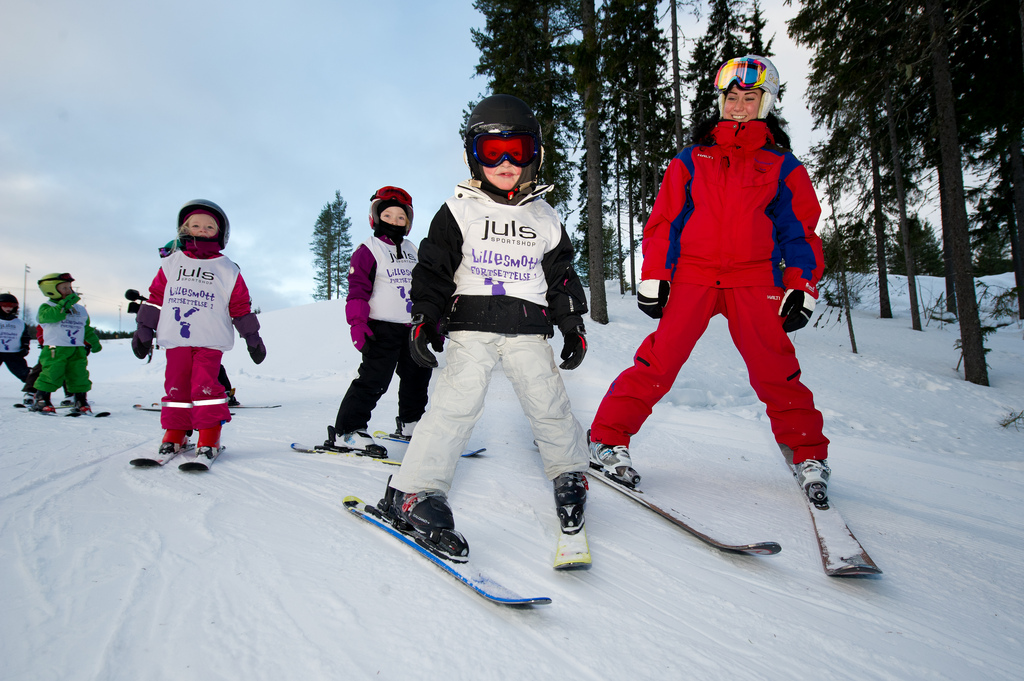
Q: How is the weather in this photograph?
A: It is cloudy.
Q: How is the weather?
A: It is cloudy.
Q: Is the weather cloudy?
A: Yes, it is cloudy.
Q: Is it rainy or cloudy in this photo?
A: It is cloudy.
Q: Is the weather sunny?
A: No, it is cloudy.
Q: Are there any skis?
A: Yes, there are skis.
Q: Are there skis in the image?
A: Yes, there are skis.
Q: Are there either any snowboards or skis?
A: Yes, there are skis.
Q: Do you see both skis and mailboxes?
A: No, there are skis but no mailboxes.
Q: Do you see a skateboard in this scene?
A: No, there are no skateboards.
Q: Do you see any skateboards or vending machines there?
A: No, there are no skateboards or vending machines.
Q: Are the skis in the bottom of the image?
A: Yes, the skis are in the bottom of the image.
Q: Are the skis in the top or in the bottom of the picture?
A: The skis are in the bottom of the image.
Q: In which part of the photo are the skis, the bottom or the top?
A: The skis are in the bottom of the image.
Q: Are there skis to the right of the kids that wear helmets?
A: Yes, there are skis to the right of the children.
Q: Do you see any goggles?
A: Yes, there are goggles.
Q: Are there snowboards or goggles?
A: Yes, there are goggles.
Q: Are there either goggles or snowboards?
A: Yes, there are goggles.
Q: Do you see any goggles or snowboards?
A: Yes, there are goggles.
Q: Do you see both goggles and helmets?
A: Yes, there are both goggles and a helmet.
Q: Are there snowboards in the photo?
A: No, there are no snowboards.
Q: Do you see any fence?
A: No, there are no fences.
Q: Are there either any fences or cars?
A: No, there are no fences or cars.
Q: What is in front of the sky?
A: The trees are in front of the sky.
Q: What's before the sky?
A: The trees are in front of the sky.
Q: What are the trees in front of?
A: The trees are in front of the sky.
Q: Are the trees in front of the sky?
A: Yes, the trees are in front of the sky.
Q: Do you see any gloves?
A: Yes, there are gloves.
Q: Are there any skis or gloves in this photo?
A: Yes, there are gloves.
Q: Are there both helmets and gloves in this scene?
A: Yes, there are both gloves and a helmet.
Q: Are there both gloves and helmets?
A: Yes, there are both gloves and a helmet.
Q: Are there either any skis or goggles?
A: Yes, there are goggles.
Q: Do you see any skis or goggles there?
A: Yes, there are goggles.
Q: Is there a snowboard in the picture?
A: No, there are no snowboards.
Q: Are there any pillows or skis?
A: Yes, there are skis.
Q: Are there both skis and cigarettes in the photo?
A: No, there are skis but no cigarettes.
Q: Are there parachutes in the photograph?
A: No, there are no parachutes.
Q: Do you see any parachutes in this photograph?
A: No, there are no parachutes.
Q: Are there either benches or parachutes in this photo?
A: No, there are no parachutes or benches.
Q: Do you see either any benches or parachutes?
A: No, there are no parachutes or benches.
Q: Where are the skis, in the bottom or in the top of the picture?
A: The skis are in the bottom of the image.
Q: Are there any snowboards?
A: No, there are no snowboards.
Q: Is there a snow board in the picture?
A: No, there are no snowboards.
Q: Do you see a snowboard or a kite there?
A: No, there are no snowboards or kites.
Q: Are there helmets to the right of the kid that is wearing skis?
A: Yes, there are helmets to the right of the kid.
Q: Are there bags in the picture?
A: No, there are no bags.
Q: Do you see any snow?
A: Yes, there is snow.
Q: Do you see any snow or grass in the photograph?
A: Yes, there is snow.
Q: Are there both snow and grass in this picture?
A: No, there is snow but no grass.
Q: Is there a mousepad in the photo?
A: No, there are no mouse pads.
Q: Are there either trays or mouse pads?
A: No, there are no mouse pads or trays.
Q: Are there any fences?
A: No, there are no fences.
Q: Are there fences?
A: No, there are no fences.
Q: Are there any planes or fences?
A: No, there are no fences or planes.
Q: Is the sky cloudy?
A: Yes, the sky is cloudy.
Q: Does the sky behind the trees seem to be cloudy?
A: Yes, the sky is cloudy.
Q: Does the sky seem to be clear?
A: No, the sky is cloudy.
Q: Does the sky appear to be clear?
A: No, the sky is cloudy.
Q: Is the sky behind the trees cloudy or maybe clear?
A: The sky is cloudy.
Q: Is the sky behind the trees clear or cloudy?
A: The sky is cloudy.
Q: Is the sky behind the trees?
A: Yes, the sky is behind the trees.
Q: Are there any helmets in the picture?
A: Yes, there is a helmet.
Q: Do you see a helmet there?
A: Yes, there is a helmet.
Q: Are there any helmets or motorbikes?
A: Yes, there is a helmet.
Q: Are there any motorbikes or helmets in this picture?
A: Yes, there is a helmet.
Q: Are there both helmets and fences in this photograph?
A: No, there is a helmet but no fences.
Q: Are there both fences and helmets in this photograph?
A: No, there is a helmet but no fences.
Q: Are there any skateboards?
A: No, there are no skateboards.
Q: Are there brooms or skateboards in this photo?
A: No, there are no skateboards or brooms.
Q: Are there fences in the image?
A: No, there are no fences.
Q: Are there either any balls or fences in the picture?
A: No, there are no fences or balls.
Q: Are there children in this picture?
A: Yes, there is a child.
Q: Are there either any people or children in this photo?
A: Yes, there is a child.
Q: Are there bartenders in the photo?
A: No, there are no bartenders.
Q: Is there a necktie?
A: No, there are no ties.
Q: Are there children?
A: Yes, there are children.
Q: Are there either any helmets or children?
A: Yes, there are children.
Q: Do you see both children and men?
A: No, there are children but no men.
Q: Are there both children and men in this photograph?
A: No, there are children but no men.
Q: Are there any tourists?
A: No, there are no tourists.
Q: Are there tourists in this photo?
A: No, there are no tourists.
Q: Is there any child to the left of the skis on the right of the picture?
A: Yes, there are children to the left of the skis.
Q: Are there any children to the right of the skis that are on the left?
A: Yes, there are children to the right of the skis.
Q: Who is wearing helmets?
A: The kids are wearing helmets.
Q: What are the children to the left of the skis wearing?
A: The children are wearing helmets.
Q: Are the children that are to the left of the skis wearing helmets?
A: Yes, the kids are wearing helmets.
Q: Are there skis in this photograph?
A: Yes, there are skis.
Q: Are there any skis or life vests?
A: Yes, there are skis.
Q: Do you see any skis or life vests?
A: Yes, there are skis.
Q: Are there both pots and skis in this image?
A: No, there are skis but no pots.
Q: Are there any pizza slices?
A: No, there are no pizza slices.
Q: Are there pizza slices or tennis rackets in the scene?
A: No, there are no pizza slices or tennis rackets.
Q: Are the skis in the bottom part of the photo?
A: Yes, the skis are in the bottom of the image.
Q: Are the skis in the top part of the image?
A: No, the skis are in the bottom of the image.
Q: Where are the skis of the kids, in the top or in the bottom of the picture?
A: The skis are in the bottom of the image.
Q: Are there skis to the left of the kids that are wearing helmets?
A: Yes, there are skis to the left of the children.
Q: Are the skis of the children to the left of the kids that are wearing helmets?
A: Yes, the skis are to the left of the kids.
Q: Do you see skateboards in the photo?
A: No, there are no skateboards.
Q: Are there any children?
A: Yes, there is a child.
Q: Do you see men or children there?
A: Yes, there is a child.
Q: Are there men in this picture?
A: No, there are no men.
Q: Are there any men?
A: No, there are no men.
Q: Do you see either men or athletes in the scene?
A: No, there are no men or athletes.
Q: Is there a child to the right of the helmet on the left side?
A: Yes, there is a child to the right of the helmet.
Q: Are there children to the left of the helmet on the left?
A: No, the child is to the right of the helmet.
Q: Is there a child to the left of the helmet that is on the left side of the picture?
A: No, the child is to the right of the helmet.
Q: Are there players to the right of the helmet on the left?
A: No, there is a child to the right of the helmet.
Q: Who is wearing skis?
A: The kid is wearing skis.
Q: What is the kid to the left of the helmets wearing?
A: The kid is wearing skis.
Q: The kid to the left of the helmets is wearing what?
A: The kid is wearing skis.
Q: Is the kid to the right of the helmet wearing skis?
A: Yes, the child is wearing skis.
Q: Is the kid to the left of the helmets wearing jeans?
A: No, the child is wearing skis.